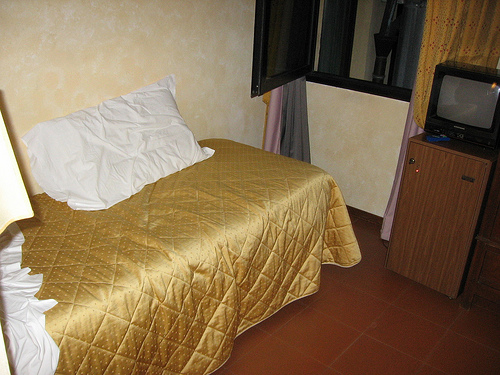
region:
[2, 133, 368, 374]
twin bed with a gold bedspread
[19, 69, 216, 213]
white pillow on the bed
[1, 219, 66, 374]
top of a white sheet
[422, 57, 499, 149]
small TV on a stand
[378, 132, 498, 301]
cheap wooden cabinet under the TV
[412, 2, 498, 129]
a yellow patterned curtain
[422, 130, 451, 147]
blue TV remote control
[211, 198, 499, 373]
reddish brown tile on the floor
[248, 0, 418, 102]
an open door on the wall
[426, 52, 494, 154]
The TV is off.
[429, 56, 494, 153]
The TV is small.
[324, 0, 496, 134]
The curtain is yellow.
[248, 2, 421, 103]
The window is open.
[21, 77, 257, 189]
The pillow is white.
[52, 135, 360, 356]
The bedspread is gold.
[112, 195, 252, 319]
The bedspread is shiny.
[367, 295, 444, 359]
The floor tile is brown.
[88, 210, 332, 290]
The gold bedspread on the bed.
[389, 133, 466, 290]
A small refrigerator.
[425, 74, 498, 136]
The television is on top of the refrigerator.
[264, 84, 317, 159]
Curtain on the wall.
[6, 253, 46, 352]
The sheets is white.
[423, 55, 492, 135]
The television is black and small.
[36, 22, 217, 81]
The wall is yellow and white.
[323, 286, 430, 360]
The floor is tiled.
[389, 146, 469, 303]
The refrigerator door is brown.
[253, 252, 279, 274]
patch of gold quilt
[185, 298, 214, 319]
patch of gold quilt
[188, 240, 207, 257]
patch of gold quilt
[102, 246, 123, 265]
patch of gold quilt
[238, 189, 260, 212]
patch of gold quilt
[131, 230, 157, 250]
patch of gold quilt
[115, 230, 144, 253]
patch of gold quilt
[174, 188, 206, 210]
patch of gold quilt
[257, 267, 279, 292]
patch of gold quilt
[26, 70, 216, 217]
pillow leans against wall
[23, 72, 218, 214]
pillow on top of bed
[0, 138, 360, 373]
golden blanket covers bed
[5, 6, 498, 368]
a bedroom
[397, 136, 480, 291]
a small brown stand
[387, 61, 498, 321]
a television on a stand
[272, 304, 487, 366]
red carpet on the floor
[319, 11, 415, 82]
a window in the room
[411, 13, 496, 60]
curtains on the window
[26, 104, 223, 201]
a white pillow on the bed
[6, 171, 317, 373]
a bed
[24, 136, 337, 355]
a yellow blanket on the bed